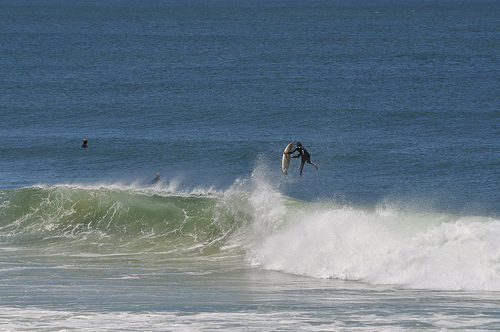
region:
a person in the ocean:
[76, 135, 91, 150]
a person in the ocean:
[147, 170, 168, 185]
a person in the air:
[284, 138, 324, 178]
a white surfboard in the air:
[280, 141, 292, 176]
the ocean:
[3, 8, 498, 329]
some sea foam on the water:
[1, 300, 492, 330]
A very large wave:
[1, 180, 498, 289]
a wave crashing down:
[238, 186, 498, 290]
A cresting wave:
[0, 183, 243, 243]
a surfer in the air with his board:
[278, 140, 320, 177]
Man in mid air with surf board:
[258, 118, 367, 257]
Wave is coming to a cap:
[135, 152, 339, 324]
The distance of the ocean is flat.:
[347, 58, 449, 135]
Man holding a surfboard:
[266, 120, 306, 176]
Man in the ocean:
[67, 111, 117, 163]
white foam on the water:
[248, 303, 364, 323]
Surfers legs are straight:
[284, 122, 324, 182]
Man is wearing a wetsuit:
[283, 134, 325, 162]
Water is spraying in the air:
[351, 173, 436, 195]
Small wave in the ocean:
[200, 88, 272, 114]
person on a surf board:
[279, 139, 318, 176]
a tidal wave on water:
[90, 188, 495, 316]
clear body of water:
[152, 33, 491, 115]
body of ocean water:
[146, 35, 480, 111]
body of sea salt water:
[150, 23, 482, 106]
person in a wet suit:
[286, 138, 324, 176]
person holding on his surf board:
[269, 130, 333, 188]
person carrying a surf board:
[277, 126, 321, 188]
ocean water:
[45, 268, 449, 330]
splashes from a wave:
[245, 193, 497, 288]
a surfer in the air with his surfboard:
[279, 137, 321, 177]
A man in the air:
[284, 138, 318, 176]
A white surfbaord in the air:
[280, 140, 294, 175]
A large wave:
[1, 181, 498, 293]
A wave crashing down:
[245, 183, 499, 293]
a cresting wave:
[0, 183, 247, 252]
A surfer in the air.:
[280, 140, 319, 180]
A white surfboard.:
[279, 140, 292, 174]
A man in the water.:
[80, 136, 89, 148]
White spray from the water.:
[251, 157, 282, 189]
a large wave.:
[5, 178, 242, 254]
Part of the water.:
[167, 98, 234, 133]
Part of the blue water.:
[391, 37, 451, 86]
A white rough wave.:
[360, 210, 495, 289]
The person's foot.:
[311, 162, 319, 169]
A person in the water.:
[145, 172, 165, 185]